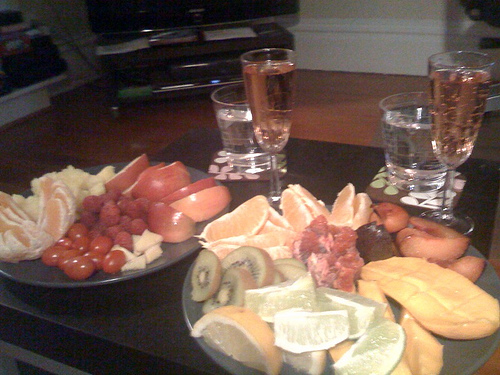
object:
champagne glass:
[418, 50, 495, 239]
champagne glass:
[238, 47, 299, 212]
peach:
[370, 202, 486, 284]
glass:
[416, 48, 496, 236]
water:
[225, 121, 251, 135]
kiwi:
[188, 245, 308, 315]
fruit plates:
[180, 203, 500, 374]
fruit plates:
[0, 161, 231, 289]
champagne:
[238, 62, 298, 156]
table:
[0, 125, 499, 375]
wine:
[430, 70, 493, 167]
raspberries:
[80, 187, 151, 253]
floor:
[296, 75, 383, 134]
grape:
[102, 249, 125, 275]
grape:
[63, 255, 95, 280]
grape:
[41, 245, 68, 266]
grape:
[66, 223, 88, 242]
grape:
[88, 235, 113, 256]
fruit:
[0, 152, 234, 281]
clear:
[240, 46, 297, 157]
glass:
[211, 83, 277, 174]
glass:
[377, 91, 456, 194]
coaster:
[207, 147, 288, 183]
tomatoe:
[102, 249, 126, 275]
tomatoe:
[61, 255, 96, 280]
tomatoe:
[55, 249, 82, 271]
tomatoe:
[89, 235, 114, 255]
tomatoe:
[55, 237, 72, 249]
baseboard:
[298, 13, 428, 78]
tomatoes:
[367, 202, 486, 284]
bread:
[358, 256, 500, 342]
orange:
[188, 305, 282, 375]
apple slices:
[104, 152, 232, 243]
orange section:
[42, 199, 60, 239]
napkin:
[363, 166, 468, 211]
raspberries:
[288, 213, 365, 294]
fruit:
[188, 183, 487, 374]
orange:
[192, 182, 375, 262]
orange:
[0, 176, 79, 264]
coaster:
[366, 164, 466, 213]